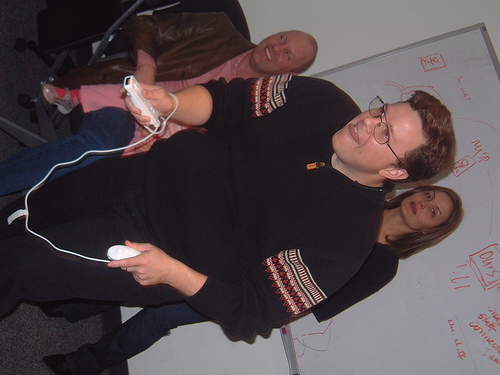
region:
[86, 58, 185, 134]
Wii controller in man's hand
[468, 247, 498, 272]
Red writing on a white board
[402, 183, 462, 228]
Woman looking at the camera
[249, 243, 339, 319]
Design on sleeve of sweater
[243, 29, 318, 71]
man looking on and smiling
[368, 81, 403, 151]
Man with glasses on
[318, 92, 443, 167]
man with tongue sticking out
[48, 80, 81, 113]
red socks on a foot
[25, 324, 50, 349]
Blue carpet on the floor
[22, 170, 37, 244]
White chord of controller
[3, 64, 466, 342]
A man is in the foreground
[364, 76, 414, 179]
Man is wearing eyeglasses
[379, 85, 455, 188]
Man has short hair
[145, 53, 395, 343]
Man is wearing a black sweater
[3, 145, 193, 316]
Man is wearing black jeans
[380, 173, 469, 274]
Woman is in the background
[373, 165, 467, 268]
Woman has brown colored hair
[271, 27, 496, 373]
A white drawing board in the background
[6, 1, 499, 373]
The photo is at a side view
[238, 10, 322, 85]
Man in the background is smiling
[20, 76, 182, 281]
Man holding video game controller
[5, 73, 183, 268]
Man holding Nintendo Wii controller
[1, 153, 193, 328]
Man wearing black pants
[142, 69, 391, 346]
Man wearing black sweater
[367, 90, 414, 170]
Man is wearing glasses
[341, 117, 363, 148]
Man has tongue hanging out of mouth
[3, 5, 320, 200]
Man is sitting down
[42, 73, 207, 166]
Child sitting on man's lap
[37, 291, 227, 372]
Woman wearing blue jeans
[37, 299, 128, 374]
Woman wearing black shoes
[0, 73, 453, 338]
man wearing a black shirt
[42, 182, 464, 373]
'woman wearing a black shirt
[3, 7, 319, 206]
man wearing brown jacket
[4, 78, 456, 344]
man holding white game controller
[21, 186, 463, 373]
woman wearing dark blue jeans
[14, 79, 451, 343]
man wearing black glasses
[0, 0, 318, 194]
man sitting in a chair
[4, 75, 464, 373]
man standing in front of woman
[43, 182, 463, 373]
woman standing in front of white board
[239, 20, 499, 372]
white board hanging on wall.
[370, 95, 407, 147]
The glasses the guy is wearing.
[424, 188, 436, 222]
The eyes of the woman.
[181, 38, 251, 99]
The pink shirt the guy on the left is wearing.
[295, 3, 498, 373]
The dry erase board behind the people.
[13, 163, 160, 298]
The black pants the guy is wearing.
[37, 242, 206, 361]
The blue jeans the lady is wearing.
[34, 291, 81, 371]
The black boots the lady is wearing.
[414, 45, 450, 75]
The stick figure on the dry erase board.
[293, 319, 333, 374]
The scribbled writing behind the lady.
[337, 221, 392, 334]
The black sleeve the shirt the lady is wearing.